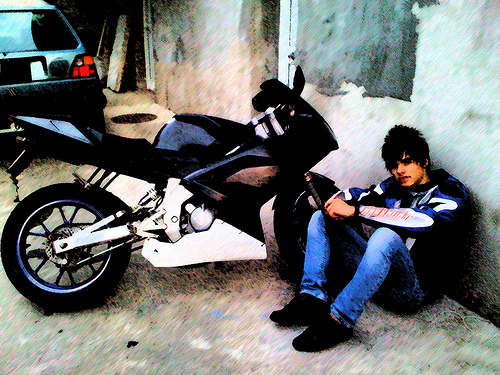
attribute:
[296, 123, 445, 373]
boy — sitting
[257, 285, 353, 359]
shoes — black, blacky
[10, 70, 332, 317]
motorcycle — black, parked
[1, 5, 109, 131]
car — parked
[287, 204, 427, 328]
jeans — blue